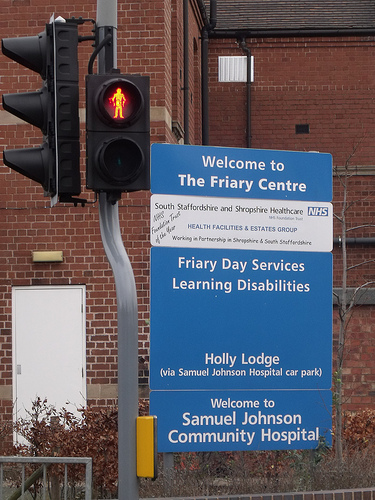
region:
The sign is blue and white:
[152, 143, 332, 447]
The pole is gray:
[117, 340, 136, 498]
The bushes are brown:
[0, 399, 373, 476]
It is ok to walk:
[95, 77, 154, 133]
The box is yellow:
[130, 413, 177, 482]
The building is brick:
[233, 32, 369, 119]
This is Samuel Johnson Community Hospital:
[166, 401, 323, 473]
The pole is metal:
[118, 351, 149, 496]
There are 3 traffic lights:
[5, 29, 96, 208]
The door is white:
[8, 353, 115, 469]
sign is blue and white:
[143, 126, 361, 459]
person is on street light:
[90, 76, 145, 121]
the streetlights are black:
[0, 0, 165, 196]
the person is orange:
[89, 72, 164, 158]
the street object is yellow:
[115, 379, 199, 488]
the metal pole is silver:
[75, 184, 159, 498]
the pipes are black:
[172, 0, 275, 155]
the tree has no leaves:
[308, 145, 372, 415]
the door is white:
[7, 280, 87, 496]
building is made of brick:
[2, 181, 205, 412]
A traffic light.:
[1, 19, 86, 211]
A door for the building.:
[6, 279, 93, 453]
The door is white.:
[9, 280, 89, 456]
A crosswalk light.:
[76, 52, 154, 199]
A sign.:
[138, 136, 339, 453]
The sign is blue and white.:
[140, 136, 332, 448]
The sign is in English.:
[141, 140, 338, 454]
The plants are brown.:
[12, 400, 120, 495]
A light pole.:
[77, 1, 146, 498]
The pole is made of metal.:
[84, 0, 148, 497]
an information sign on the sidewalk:
[148, 141, 331, 449]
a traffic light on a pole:
[1, 17, 81, 201]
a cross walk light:
[85, 73, 151, 193]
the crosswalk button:
[134, 415, 157, 479]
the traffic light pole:
[97, 192, 137, 493]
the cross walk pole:
[98, 193, 137, 497]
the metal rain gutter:
[201, 29, 209, 145]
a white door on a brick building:
[12, 286, 85, 452]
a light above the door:
[31, 249, 63, 261]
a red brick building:
[149, 0, 374, 143]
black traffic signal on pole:
[89, 76, 150, 182]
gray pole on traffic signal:
[91, 208, 155, 442]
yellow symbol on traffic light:
[105, 88, 136, 113]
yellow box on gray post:
[123, 408, 175, 478]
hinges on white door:
[58, 292, 93, 383]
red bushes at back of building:
[19, 401, 115, 444]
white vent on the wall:
[202, 48, 271, 85]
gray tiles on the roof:
[241, 4, 332, 18]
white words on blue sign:
[182, 388, 294, 432]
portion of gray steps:
[14, 446, 109, 487]